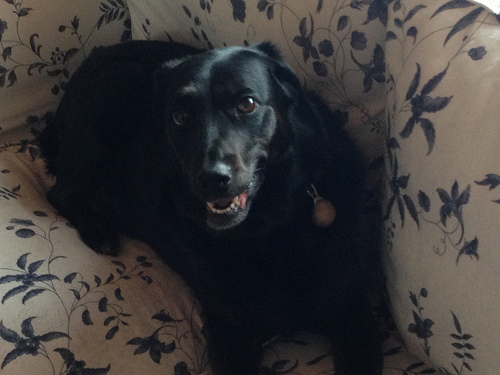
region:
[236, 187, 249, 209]
The black dog's tongue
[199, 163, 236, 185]
The black dog's nose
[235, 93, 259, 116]
The black dog's left eye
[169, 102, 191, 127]
The black dog's right eye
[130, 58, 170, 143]
The black dog's right ear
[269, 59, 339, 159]
The black dog's left ear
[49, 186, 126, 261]
The black dog's back right paw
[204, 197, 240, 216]
The black dog's teeth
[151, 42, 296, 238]
The black dog's head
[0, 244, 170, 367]
white and blue floral pattern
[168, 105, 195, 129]
eye on the dog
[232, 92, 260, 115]
eye on the dog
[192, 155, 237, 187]
nose on the dog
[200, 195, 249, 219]
teeth on the dog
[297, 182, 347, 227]
tag on the dog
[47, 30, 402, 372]
black dog on couch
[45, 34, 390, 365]
the dog is black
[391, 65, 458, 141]
blue flower on couch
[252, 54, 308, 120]
ear on the dog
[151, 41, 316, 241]
head on the dog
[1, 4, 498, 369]
large black dog on a sofa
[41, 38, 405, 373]
a happy smiling black dog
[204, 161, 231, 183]
black dog's nose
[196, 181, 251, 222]
dog smile showing bottom teeth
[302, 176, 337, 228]
dog tag on dog collar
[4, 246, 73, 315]
bamboo sofa fabric pattern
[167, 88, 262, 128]
alert and sparkly dog eyes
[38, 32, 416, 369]
large happy black labrador mix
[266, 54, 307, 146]
black dog's floppy ear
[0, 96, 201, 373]
bamboo patterned sofa cushion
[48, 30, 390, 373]
Black dog on sofa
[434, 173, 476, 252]
Blue flower on sofa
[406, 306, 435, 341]
Blue flower on sofa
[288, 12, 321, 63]
Blue flower on sofa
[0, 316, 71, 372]
Blue flower on sofa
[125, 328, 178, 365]
Blue flower on sofa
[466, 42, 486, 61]
Blue flower on sofa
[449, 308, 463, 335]
Blue leaf on sofa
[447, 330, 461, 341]
Blue leaf on sofa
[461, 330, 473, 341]
Blue leaf on sofa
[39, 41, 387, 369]
a black dog on a couch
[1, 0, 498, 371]
a white couch with blue floral design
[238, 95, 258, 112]
a dog's brown eye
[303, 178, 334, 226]
a tag on a dog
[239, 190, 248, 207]
a pink gum in a dog's mouth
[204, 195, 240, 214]
a dog's bottom row of teeth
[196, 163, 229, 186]
a black dog nose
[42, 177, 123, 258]
the hind leg of a black dog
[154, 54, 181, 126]
a black ear on a dog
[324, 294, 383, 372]
the front leg of a dog